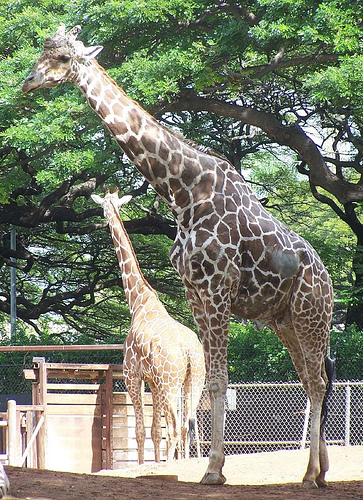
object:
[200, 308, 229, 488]
leg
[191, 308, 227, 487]
leg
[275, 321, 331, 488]
leg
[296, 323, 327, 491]
leg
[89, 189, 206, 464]
giraffe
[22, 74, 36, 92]
nose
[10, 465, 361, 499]
shadow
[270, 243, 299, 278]
patch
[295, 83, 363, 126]
wall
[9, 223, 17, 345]
pole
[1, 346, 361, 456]
fence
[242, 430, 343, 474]
ground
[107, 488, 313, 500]
dirt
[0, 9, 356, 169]
trees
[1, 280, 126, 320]
large branch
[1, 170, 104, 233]
large branch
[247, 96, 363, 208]
large branch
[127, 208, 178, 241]
large branch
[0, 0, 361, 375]
tree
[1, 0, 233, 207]
tree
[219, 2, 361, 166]
tree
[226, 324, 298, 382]
tree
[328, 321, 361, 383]
tree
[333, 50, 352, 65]
leaf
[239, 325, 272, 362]
leaf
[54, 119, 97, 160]
leaf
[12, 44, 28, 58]
leaf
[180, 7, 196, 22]
leaf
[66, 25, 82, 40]
ear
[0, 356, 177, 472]
slats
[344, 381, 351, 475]
rails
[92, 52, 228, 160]
mane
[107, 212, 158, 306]
neck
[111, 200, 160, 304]
mane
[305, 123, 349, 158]
sky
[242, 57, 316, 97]
branches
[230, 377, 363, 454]
fence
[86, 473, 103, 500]
dirt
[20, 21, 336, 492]
giraffe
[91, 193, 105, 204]
ear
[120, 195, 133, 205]
ear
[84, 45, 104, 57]
ear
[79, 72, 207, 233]
neck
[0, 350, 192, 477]
structure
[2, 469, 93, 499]
dirt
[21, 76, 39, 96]
mouth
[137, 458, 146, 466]
foot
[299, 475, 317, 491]
foot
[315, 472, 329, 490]
foot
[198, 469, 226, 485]
foot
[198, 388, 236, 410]
sticker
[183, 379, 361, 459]
fence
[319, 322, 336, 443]
giraffe tail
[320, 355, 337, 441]
black hair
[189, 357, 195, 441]
tail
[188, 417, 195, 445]
hair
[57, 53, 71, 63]
eye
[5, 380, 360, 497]
enclosure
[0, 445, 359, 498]
ground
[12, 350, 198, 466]
fence